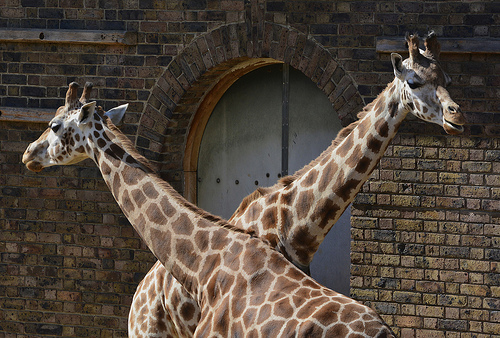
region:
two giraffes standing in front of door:
[17, 35, 460, 335]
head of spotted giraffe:
[12, 90, 137, 191]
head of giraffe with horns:
[382, 34, 469, 146]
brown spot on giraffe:
[209, 272, 231, 299]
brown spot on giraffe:
[292, 188, 313, 218]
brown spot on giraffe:
[266, 298, 293, 317]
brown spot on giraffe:
[243, 251, 259, 273]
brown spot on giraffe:
[196, 232, 212, 252]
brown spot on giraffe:
[145, 211, 163, 227]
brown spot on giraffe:
[345, 317, 362, 332]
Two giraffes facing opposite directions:
[20, 11, 472, 334]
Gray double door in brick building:
[151, 7, 356, 215]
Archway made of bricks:
[164, 0, 399, 118]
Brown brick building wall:
[372, 169, 492, 316]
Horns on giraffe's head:
[403, 25, 440, 71]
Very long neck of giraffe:
[256, 83, 394, 268]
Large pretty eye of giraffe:
[40, 115, 67, 139]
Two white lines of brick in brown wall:
[0, 15, 118, 123]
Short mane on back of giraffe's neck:
[243, 140, 343, 203]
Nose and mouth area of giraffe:
[431, 89, 468, 150]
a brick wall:
[386, 222, 446, 320]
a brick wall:
[472, 120, 494, 154]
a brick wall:
[416, 256, 484, 331]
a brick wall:
[416, 195, 496, 327]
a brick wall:
[411, 140, 467, 308]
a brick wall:
[363, 180, 480, 324]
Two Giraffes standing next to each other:
[9, 18, 490, 265]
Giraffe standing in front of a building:
[349, 38, 476, 171]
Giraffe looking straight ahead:
[6, 87, 150, 193]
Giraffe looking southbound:
[378, 35, 478, 169]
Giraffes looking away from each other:
[21, 35, 487, 267]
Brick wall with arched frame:
[160, 39, 372, 146]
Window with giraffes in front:
[192, 72, 361, 292]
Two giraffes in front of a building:
[55, 47, 434, 283]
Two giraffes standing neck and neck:
[66, 95, 384, 256]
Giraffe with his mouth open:
[376, 27, 473, 154]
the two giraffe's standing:
[17, 22, 466, 335]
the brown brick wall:
[385, 170, 493, 318]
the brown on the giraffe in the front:
[215, 267, 277, 335]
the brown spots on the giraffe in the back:
[257, 193, 312, 238]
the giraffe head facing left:
[22, 77, 117, 165]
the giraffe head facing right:
[390, 22, 465, 135]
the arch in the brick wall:
[132, 22, 373, 323]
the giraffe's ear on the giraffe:
[74, 98, 130, 129]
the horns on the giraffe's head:
[60, 76, 92, 105]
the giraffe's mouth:
[21, 147, 41, 176]